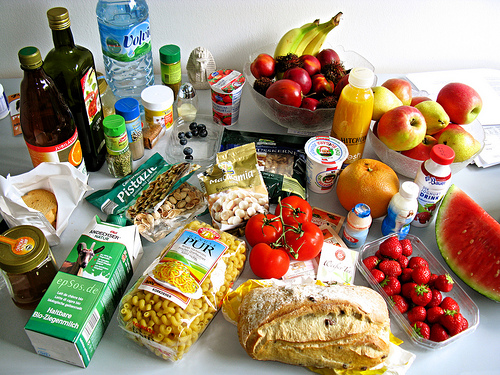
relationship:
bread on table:
[205, 272, 399, 367] [9, 68, 497, 366]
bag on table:
[87, 150, 223, 248] [9, 68, 497, 366]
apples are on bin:
[369, 80, 476, 177] [352, 128, 459, 211]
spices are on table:
[97, 81, 187, 182] [9, 68, 497, 366]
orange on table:
[333, 150, 397, 220] [9, 68, 497, 366]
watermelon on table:
[427, 179, 497, 306] [9, 68, 497, 366]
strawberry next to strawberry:
[377, 236, 412, 262] [402, 280, 437, 319]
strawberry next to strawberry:
[373, 244, 405, 284] [405, 251, 431, 293]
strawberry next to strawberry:
[377, 234, 412, 266] [402, 256, 432, 285]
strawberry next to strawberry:
[372, 236, 412, 266] [402, 247, 432, 287]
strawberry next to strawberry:
[369, 229, 405, 261] [403, 266, 430, 306]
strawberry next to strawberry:
[374, 234, 406, 262] [395, 266, 432, 308]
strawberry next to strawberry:
[399, 274, 435, 308] [400, 303, 434, 334]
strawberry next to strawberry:
[409, 277, 436, 311] [400, 296, 431, 324]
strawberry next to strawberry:
[369, 226, 417, 269] [402, 280, 432, 322]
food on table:
[2, 11, 492, 371] [9, 68, 497, 366]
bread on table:
[238, 280, 391, 371] [9, 68, 497, 366]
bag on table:
[103, 218, 249, 368] [9, 68, 497, 366]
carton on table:
[356, 232, 480, 352] [9, 68, 497, 366]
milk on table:
[22, 230, 112, 365] [59, 70, 497, 362]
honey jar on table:
[0, 216, 57, 306] [9, 68, 497, 366]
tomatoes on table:
[243, 188, 323, 280] [9, 68, 497, 366]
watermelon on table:
[436, 184, 500, 305] [9, 68, 497, 366]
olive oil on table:
[39, 5, 111, 172] [9, 68, 497, 366]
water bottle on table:
[93, 0, 158, 98] [9, 68, 497, 366]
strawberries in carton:
[406, 281, 458, 332] [352, 221, 482, 351]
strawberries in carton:
[382, 242, 435, 304] [356, 232, 480, 352]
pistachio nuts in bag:
[161, 174, 185, 196] [94, 152, 204, 229]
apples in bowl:
[390, 103, 460, 133] [368, 131, 461, 192]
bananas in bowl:
[278, 17, 327, 49] [240, 55, 376, 133]